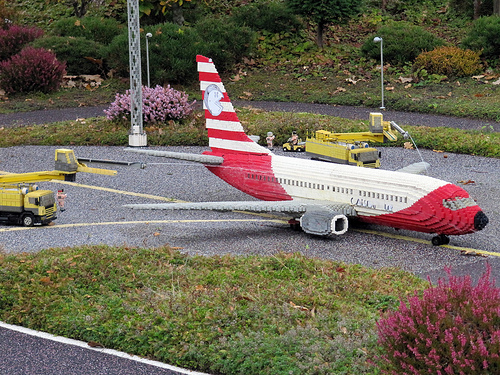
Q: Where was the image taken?
A: It was taken at the pavement.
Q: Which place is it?
A: It is a pavement.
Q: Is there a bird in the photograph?
A: No, there are no birds.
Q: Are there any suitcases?
A: No, there are no suitcases.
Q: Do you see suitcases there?
A: No, there are no suitcases.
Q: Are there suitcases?
A: No, there are no suitcases.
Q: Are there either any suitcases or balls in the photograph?
A: No, there are no suitcases or balls.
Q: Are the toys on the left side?
A: Yes, the toys are on the left of the image.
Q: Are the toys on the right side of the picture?
A: No, the toys are on the left of the image.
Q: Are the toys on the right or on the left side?
A: The toys are on the left of the image.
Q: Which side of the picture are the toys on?
A: The toys are on the left of the image.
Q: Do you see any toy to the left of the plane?
A: Yes, there are toys to the left of the plane.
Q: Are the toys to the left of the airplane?
A: Yes, the toys are to the left of the airplane.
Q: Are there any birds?
A: No, there are no birds.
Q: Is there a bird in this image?
A: No, there are no birds.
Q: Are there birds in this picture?
A: No, there are no birds.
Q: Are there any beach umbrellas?
A: No, there are no beach umbrellas.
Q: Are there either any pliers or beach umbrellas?
A: No, there are no beach umbrellas or pliers.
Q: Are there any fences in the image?
A: No, there are no fences.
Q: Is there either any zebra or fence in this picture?
A: No, there are no fences or zebras.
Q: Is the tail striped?
A: Yes, the tail is striped.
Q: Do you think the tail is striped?
A: Yes, the tail is striped.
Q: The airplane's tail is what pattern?
A: The tail is striped.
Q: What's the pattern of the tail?
A: The tail is striped.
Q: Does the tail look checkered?
A: No, the tail is striped.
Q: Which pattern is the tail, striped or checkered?
A: The tail is striped.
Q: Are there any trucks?
A: Yes, there is a truck.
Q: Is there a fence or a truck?
A: Yes, there is a truck.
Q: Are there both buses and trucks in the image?
A: No, there is a truck but no buses.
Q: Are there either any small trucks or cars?
A: Yes, there is a small truck.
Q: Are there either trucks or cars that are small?
A: Yes, the truck is small.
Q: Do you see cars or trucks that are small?
A: Yes, the truck is small.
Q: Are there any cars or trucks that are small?
A: Yes, the truck is small.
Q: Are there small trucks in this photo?
A: Yes, there is a small truck.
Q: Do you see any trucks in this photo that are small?
A: Yes, there is a truck that is small.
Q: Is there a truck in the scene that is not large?
A: Yes, there is a small truck.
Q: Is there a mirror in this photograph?
A: No, there are no mirrors.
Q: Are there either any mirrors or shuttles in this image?
A: No, there are no mirrors or shuttles.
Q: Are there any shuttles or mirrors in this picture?
A: No, there are no mirrors or shuttles.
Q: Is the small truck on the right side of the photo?
A: Yes, the truck is on the right of the image.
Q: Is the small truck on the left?
A: No, the truck is on the right of the image.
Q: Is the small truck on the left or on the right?
A: The truck is on the right of the image.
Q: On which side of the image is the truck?
A: The truck is on the right of the image.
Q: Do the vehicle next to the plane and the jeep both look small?
A: Yes, both the truck and the jeep are small.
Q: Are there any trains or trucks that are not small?
A: No, there is a truck but it is small.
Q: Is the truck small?
A: Yes, the truck is small.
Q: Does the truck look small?
A: Yes, the truck is small.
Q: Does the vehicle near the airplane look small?
A: Yes, the truck is small.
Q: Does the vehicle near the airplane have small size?
A: Yes, the truck is small.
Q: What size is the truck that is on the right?
A: The truck is small.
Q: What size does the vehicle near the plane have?
A: The truck has small size.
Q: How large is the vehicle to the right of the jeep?
A: The truck is small.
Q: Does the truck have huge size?
A: No, the truck is small.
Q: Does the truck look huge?
A: No, the truck is small.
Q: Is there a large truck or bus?
A: No, there is a truck but it is small.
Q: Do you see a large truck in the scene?
A: No, there is a truck but it is small.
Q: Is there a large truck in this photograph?
A: No, there is a truck but it is small.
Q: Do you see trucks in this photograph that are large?
A: No, there is a truck but it is small.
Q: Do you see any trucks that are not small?
A: No, there is a truck but it is small.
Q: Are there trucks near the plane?
A: Yes, there is a truck near the plane.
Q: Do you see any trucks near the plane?
A: Yes, there is a truck near the plane.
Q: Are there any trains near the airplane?
A: No, there is a truck near the airplane.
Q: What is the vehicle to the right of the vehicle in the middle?
A: The vehicle is a truck.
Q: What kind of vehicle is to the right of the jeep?
A: The vehicle is a truck.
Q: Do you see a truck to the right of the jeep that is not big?
A: Yes, there is a truck to the right of the jeep.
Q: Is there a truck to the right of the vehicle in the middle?
A: Yes, there is a truck to the right of the jeep.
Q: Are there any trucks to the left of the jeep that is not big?
A: No, the truck is to the right of the jeep.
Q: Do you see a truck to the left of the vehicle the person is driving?
A: No, the truck is to the right of the jeep.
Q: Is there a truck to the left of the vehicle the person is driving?
A: No, the truck is to the right of the jeep.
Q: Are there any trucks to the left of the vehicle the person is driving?
A: No, the truck is to the right of the jeep.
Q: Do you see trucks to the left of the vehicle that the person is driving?
A: No, the truck is to the right of the jeep.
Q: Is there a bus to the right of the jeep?
A: No, there is a truck to the right of the jeep.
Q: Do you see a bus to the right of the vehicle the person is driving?
A: No, there is a truck to the right of the jeep.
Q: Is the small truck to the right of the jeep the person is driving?
A: Yes, the truck is to the right of the jeep.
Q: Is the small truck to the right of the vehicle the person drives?
A: Yes, the truck is to the right of the jeep.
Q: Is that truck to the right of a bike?
A: No, the truck is to the right of the jeep.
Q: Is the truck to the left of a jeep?
A: No, the truck is to the right of a jeep.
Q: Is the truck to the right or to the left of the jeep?
A: The truck is to the right of the jeep.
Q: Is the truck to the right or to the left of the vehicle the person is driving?
A: The truck is to the right of the jeep.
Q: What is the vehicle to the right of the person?
A: The vehicle is a truck.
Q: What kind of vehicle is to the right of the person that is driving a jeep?
A: The vehicle is a truck.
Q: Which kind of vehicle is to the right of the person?
A: The vehicle is a truck.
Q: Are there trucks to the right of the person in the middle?
A: Yes, there is a truck to the right of the person.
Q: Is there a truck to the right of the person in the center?
A: Yes, there is a truck to the right of the person.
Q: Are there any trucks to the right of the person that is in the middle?
A: Yes, there is a truck to the right of the person.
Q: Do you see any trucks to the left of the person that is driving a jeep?
A: No, the truck is to the right of the person.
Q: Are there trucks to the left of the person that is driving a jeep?
A: No, the truck is to the right of the person.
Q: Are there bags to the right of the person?
A: No, there is a truck to the right of the person.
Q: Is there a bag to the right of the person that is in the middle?
A: No, there is a truck to the right of the person.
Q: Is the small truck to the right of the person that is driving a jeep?
A: Yes, the truck is to the right of the person.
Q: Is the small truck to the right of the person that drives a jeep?
A: Yes, the truck is to the right of the person.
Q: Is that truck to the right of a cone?
A: No, the truck is to the right of the person.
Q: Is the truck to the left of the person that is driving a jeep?
A: No, the truck is to the right of the person.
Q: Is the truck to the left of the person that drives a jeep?
A: No, the truck is to the right of the person.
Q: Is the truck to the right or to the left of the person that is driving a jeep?
A: The truck is to the right of the person.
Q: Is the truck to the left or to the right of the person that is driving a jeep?
A: The truck is to the right of the person.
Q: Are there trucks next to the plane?
A: Yes, there is a truck next to the plane.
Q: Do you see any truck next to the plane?
A: Yes, there is a truck next to the plane.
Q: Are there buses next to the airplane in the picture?
A: No, there is a truck next to the airplane.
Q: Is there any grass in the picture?
A: Yes, there is grass.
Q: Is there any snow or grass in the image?
A: Yes, there is grass.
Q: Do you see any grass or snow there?
A: Yes, there is grass.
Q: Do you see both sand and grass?
A: No, there is grass but no sand.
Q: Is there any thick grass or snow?
A: Yes, there is thick grass.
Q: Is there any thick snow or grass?
A: Yes, there is thick grass.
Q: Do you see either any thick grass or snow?
A: Yes, there is thick grass.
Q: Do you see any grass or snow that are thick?
A: Yes, the grass is thick.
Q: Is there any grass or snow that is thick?
A: Yes, the grass is thick.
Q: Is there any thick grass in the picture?
A: Yes, there is thick grass.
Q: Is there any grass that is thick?
A: Yes, there is grass that is thick.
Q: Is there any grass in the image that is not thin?
A: Yes, there is thick grass.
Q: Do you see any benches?
A: No, there are no benches.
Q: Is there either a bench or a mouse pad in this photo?
A: No, there are no benches or mouse pads.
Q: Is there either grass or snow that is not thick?
A: No, there is grass but it is thick.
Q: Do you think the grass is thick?
A: Yes, the grass is thick.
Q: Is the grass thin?
A: No, the grass is thick.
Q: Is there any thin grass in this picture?
A: No, there is grass but it is thick.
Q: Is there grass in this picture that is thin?
A: No, there is grass but it is thick.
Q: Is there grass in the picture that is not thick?
A: No, there is grass but it is thick.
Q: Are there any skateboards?
A: No, there are no skateboards.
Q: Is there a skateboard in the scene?
A: No, there are no skateboards.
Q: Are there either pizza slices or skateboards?
A: No, there are no skateboards or pizza slices.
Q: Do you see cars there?
A: No, there are no cars.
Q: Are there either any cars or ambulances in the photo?
A: No, there are no cars or ambulances.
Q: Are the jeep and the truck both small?
A: Yes, both the jeep and the truck are small.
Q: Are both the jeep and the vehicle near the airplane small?
A: Yes, both the jeep and the truck are small.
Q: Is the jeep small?
A: Yes, the jeep is small.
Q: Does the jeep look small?
A: Yes, the jeep is small.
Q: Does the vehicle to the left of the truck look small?
A: Yes, the jeep is small.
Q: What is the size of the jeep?
A: The jeep is small.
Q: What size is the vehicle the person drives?
A: The jeep is small.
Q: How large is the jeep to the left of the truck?
A: The jeep is small.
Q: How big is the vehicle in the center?
A: The jeep is small.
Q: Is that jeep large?
A: No, the jeep is small.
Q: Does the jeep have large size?
A: No, the jeep is small.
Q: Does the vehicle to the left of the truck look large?
A: No, the jeep is small.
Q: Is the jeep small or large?
A: The jeep is small.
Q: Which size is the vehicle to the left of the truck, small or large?
A: The jeep is small.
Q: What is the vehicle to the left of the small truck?
A: The vehicle is a jeep.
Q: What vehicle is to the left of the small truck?
A: The vehicle is a jeep.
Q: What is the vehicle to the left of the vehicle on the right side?
A: The vehicle is a jeep.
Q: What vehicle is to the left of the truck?
A: The vehicle is a jeep.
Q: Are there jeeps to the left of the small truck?
A: Yes, there is a jeep to the left of the truck.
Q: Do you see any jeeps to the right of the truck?
A: No, the jeep is to the left of the truck.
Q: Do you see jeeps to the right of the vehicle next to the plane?
A: No, the jeep is to the left of the truck.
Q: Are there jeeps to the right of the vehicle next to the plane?
A: No, the jeep is to the left of the truck.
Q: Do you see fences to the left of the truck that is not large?
A: No, there is a jeep to the left of the truck.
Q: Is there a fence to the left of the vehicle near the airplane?
A: No, there is a jeep to the left of the truck.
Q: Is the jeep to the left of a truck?
A: Yes, the jeep is to the left of a truck.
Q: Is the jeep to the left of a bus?
A: No, the jeep is to the left of a truck.